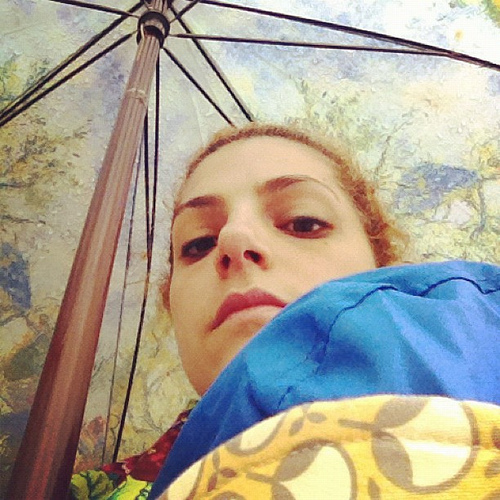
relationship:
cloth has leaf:
[137, 260, 500, 500] [347, 404, 473, 486]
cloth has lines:
[187, 261, 499, 406] [307, 273, 493, 313]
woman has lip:
[142, 122, 500, 499] [208, 287, 288, 330]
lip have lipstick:
[208, 287, 288, 330] [228, 292, 268, 308]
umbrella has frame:
[5, 4, 494, 298] [162, 2, 335, 114]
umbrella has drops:
[5, 4, 494, 298] [32, 171, 87, 251]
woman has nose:
[142, 122, 500, 499] [212, 215, 270, 276]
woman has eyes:
[142, 122, 500, 499] [173, 180, 347, 267]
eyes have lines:
[173, 180, 347, 267] [283, 228, 342, 253]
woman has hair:
[142, 122, 500, 499] [158, 122, 416, 318]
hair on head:
[158, 122, 416, 318] [149, 117, 391, 388]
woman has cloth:
[142, 122, 500, 499] [137, 260, 500, 500]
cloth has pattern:
[137, 260, 500, 500] [338, 401, 482, 491]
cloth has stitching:
[137, 260, 500, 500] [261, 428, 490, 457]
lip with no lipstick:
[208, 287, 288, 330] [228, 292, 268, 308]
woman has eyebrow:
[142, 122, 500, 499] [260, 169, 340, 198]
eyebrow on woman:
[260, 169, 340, 198] [142, 122, 500, 499]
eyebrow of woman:
[168, 193, 219, 212] [138, 117, 397, 481]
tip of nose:
[218, 224, 246, 250] [211, 222, 259, 252]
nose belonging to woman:
[205, 201, 273, 278] [70, 113, 416, 497]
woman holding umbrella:
[70, 113, 416, 497] [1, 0, 498, 497]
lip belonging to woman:
[206, 283, 294, 332] [142, 122, 500, 499]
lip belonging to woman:
[208, 300, 288, 334] [142, 122, 500, 499]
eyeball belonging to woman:
[273, 207, 337, 239] [70, 113, 416, 497]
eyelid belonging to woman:
[276, 198, 336, 222] [70, 113, 416, 497]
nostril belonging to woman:
[239, 246, 266, 269] [70, 113, 416, 497]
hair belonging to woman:
[178, 118, 416, 272] [70, 113, 416, 497]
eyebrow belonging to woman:
[260, 169, 340, 198] [70, 113, 416, 497]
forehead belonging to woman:
[171, 134, 338, 199] [70, 113, 416, 497]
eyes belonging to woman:
[178, 232, 221, 259] [70, 113, 416, 497]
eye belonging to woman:
[271, 209, 333, 236] [142, 122, 500, 499]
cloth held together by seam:
[137, 260, 500, 500] [272, 273, 484, 409]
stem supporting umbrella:
[1, 0, 145, 125] [1, 0, 498, 497]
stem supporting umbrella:
[112, 41, 158, 458] [1, 0, 498, 497]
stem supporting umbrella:
[160, 1, 257, 126] [1, 0, 498, 497]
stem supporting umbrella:
[167, 2, 499, 69] [1, 0, 498, 497]